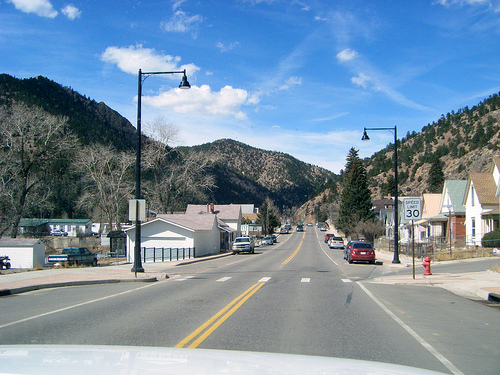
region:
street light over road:
[116, 51, 212, 314]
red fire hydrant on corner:
[352, 250, 442, 290]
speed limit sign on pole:
[397, 185, 430, 278]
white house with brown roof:
[454, 166, 499, 247]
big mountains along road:
[187, 131, 347, 241]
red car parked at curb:
[329, 234, 395, 287]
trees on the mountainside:
[405, 107, 490, 184]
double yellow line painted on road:
[182, 294, 262, 360]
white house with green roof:
[17, 211, 92, 244]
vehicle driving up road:
[290, 211, 307, 246]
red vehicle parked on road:
[346, 236, 376, 265]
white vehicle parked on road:
[231, 234, 257, 255]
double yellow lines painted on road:
[168, 278, 277, 346]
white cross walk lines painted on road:
[163, 265, 373, 289]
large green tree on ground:
[336, 146, 376, 244]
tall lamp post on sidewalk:
[113, 64, 194, 276]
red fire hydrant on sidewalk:
[423, 253, 433, 274]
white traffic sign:
[401, 196, 421, 284]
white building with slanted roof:
[127, 210, 227, 270]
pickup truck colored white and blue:
[48, 242, 100, 271]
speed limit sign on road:
[393, 193, 420, 229]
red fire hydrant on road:
[416, 251, 442, 285]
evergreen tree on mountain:
[421, 156, 440, 193]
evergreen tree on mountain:
[333, 141, 378, 221]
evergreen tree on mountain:
[459, 147, 471, 159]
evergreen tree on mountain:
[471, 135, 486, 150]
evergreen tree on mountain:
[474, 123, 488, 145]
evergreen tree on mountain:
[401, 153, 411, 165]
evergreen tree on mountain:
[487, 127, 495, 141]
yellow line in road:
[184, 304, 229, 336]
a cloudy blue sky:
[0, 0, 498, 175]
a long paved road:
[23, 195, 424, 355]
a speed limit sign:
[399, 193, 424, 281]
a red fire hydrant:
[419, 253, 434, 276]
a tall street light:
[122, 65, 192, 273]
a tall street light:
[354, 119, 405, 266]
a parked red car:
[349, 239, 374, 264]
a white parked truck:
[231, 235, 253, 252]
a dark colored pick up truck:
[48, 244, 94, 266]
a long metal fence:
[131, 244, 193, 261]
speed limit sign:
[400, 192, 421, 284]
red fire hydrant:
[420, 252, 432, 281]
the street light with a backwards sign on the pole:
[123, 60, 203, 274]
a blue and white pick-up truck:
[44, 241, 104, 271]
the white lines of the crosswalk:
[165, 268, 356, 290]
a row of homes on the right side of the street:
[380, 166, 498, 256]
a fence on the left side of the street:
[137, 245, 198, 262]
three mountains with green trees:
[22, 62, 497, 215]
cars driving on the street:
[294, 220, 314, 234]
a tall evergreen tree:
[334, 145, 381, 247]